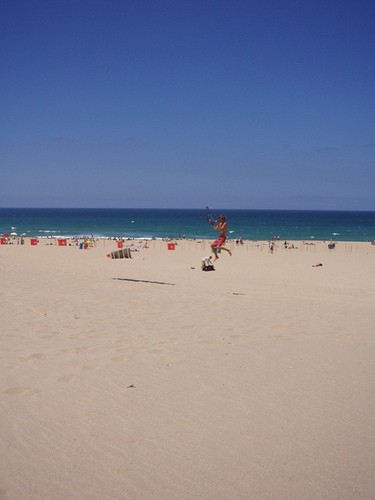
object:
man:
[200, 255, 212, 272]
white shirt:
[202, 257, 209, 263]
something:
[204, 264, 215, 270]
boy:
[208, 214, 231, 263]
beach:
[0, 236, 374, 498]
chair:
[46, 234, 51, 239]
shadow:
[112, 277, 174, 286]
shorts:
[210, 236, 227, 250]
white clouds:
[293, 117, 371, 169]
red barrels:
[30, 238, 37, 246]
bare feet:
[213, 256, 220, 263]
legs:
[210, 240, 217, 256]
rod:
[207, 217, 219, 223]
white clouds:
[197, 182, 240, 194]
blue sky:
[0, 0, 375, 214]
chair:
[123, 240, 148, 252]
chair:
[327, 241, 336, 253]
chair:
[82, 234, 92, 248]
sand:
[3, 235, 374, 498]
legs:
[216, 240, 227, 252]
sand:
[193, 245, 243, 287]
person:
[267, 238, 274, 253]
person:
[120, 232, 123, 240]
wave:
[233, 223, 313, 240]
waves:
[102, 209, 169, 226]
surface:
[116, 210, 209, 224]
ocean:
[0, 206, 374, 242]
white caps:
[36, 228, 162, 238]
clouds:
[0, 0, 375, 214]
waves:
[5, 229, 178, 241]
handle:
[204, 203, 218, 223]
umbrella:
[10, 232, 17, 240]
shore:
[3, 236, 374, 268]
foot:
[227, 249, 232, 257]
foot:
[213, 255, 219, 262]